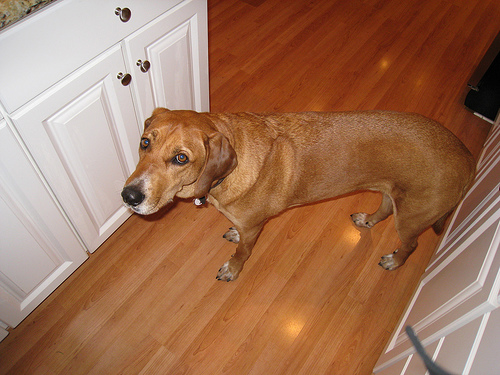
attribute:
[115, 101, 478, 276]
dog — brown, standing, camera-facing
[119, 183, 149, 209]
nose — black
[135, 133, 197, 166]
eyes — brown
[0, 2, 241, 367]
cabinet — white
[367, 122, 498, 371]
cabinet — white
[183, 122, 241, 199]
ear — hanging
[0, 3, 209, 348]
cabinet — white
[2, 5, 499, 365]
floor — wooden, pictured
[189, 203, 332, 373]
board — pictured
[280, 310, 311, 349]
light — pictured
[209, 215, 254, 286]
leg — pictured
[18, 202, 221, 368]
panels — tan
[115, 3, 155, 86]
knobs — silver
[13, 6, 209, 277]
cabinet doors — white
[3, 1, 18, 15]
countertop — granite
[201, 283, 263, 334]
floor — wood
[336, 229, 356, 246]
light — reflections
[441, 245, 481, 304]
cabinets — white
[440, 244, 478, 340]
cabinets — white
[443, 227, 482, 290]
cabinets — white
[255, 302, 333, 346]
floor — wooden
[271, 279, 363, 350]
floor — wooden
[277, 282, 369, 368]
floor — wooden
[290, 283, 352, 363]
floor — wooden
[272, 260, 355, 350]
floor — wooden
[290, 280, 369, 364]
floor — wooden